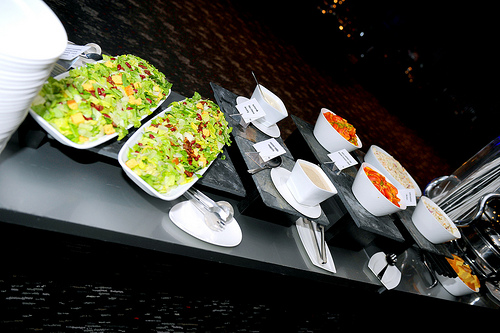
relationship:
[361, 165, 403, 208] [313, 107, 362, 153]
food in bowls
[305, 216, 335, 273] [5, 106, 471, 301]
napkins on table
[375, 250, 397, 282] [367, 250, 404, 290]
spoon on plate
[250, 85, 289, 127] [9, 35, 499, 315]
bowl on table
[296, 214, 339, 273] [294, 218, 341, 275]
tongs on plate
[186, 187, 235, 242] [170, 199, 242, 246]
tongs on plate